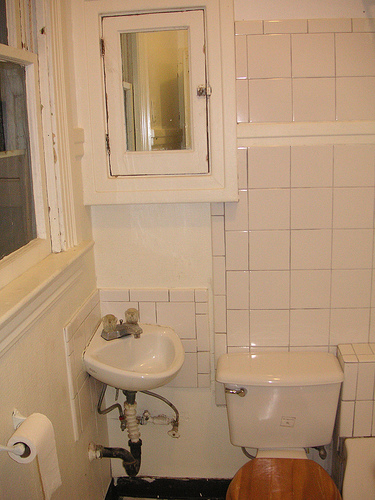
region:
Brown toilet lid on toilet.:
[225, 451, 336, 499]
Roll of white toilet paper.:
[8, 403, 67, 493]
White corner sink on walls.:
[83, 302, 186, 389]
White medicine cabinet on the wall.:
[66, 1, 247, 205]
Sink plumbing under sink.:
[90, 381, 181, 479]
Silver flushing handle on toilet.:
[220, 381, 258, 404]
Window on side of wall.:
[1, 1, 76, 294]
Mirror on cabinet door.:
[115, 28, 198, 161]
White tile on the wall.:
[243, 143, 369, 339]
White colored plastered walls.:
[90, 208, 199, 287]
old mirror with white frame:
[102, 13, 233, 185]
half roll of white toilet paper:
[10, 412, 76, 496]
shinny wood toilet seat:
[229, 453, 340, 498]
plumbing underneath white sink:
[91, 344, 174, 481]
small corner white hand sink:
[89, 305, 187, 396]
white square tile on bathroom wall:
[246, 148, 366, 320]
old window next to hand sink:
[0, 119, 144, 360]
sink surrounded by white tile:
[63, 281, 222, 427]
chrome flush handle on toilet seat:
[222, 386, 261, 411]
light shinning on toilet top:
[220, 350, 291, 428]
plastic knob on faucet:
[102, 313, 118, 328]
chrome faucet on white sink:
[102, 308, 144, 340]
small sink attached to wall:
[84, 312, 183, 395]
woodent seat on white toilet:
[223, 456, 342, 499]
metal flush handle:
[223, 385, 247, 397]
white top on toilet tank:
[214, 351, 341, 391]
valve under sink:
[167, 429, 180, 439]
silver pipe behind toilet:
[240, 446, 253, 459]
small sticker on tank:
[278, 414, 296, 428]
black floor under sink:
[106, 474, 233, 498]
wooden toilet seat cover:
[223, 455, 345, 499]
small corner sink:
[80, 307, 185, 391]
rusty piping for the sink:
[89, 389, 144, 480]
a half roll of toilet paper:
[5, 410, 65, 497]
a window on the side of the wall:
[0, 43, 55, 292]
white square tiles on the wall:
[72, 14, 374, 443]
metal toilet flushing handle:
[222, 385, 247, 397]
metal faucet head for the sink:
[99, 307, 142, 342]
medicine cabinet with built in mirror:
[99, 5, 213, 182]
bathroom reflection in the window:
[0, 61, 40, 261]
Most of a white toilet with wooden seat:
[216, 351, 344, 497]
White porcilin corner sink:
[82, 306, 184, 392]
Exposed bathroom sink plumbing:
[89, 383, 181, 479]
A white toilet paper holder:
[1, 410, 63, 499]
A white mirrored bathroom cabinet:
[71, 0, 238, 202]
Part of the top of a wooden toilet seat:
[225, 457, 342, 498]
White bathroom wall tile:
[62, 17, 373, 441]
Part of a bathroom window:
[0, 0, 53, 264]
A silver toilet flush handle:
[223, 386, 247, 396]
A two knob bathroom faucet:
[99, 307, 141, 339]